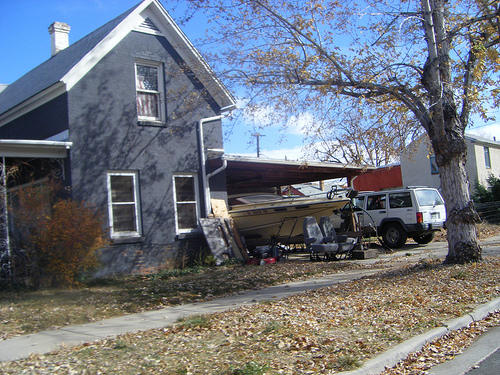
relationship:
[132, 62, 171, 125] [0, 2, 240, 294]
window on building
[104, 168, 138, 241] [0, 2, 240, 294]
window on building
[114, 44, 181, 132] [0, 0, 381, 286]
window on building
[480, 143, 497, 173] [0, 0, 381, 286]
window on building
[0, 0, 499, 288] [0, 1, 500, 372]
building on street